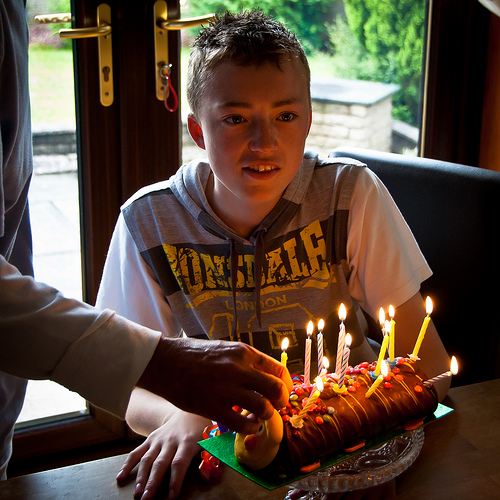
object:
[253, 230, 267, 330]
strings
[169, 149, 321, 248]
hood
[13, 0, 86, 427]
window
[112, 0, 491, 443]
door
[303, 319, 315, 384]
candle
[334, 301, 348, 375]
candle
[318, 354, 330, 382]
candle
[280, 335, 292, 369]
candle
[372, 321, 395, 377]
candle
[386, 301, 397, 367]
candle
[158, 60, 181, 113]
key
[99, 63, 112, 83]
door lock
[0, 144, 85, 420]
ground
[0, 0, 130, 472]
door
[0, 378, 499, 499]
tabletop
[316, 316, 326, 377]
candle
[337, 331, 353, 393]
candle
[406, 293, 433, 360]
candle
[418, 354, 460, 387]
candle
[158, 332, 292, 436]
hand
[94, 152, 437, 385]
tshirt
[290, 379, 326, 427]
candle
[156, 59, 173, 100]
latch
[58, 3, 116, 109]
handle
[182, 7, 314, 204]
face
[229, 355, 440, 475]
cake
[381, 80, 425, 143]
foilage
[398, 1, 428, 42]
foilage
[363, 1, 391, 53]
foilage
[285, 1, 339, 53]
foilage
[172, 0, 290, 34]
foilage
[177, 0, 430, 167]
window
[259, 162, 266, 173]
teeth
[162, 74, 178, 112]
loop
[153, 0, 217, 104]
handle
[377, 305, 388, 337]
candle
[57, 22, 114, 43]
handle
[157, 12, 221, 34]
handle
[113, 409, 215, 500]
hand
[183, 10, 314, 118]
hair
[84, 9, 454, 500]
boy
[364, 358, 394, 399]
candle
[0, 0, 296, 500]
man